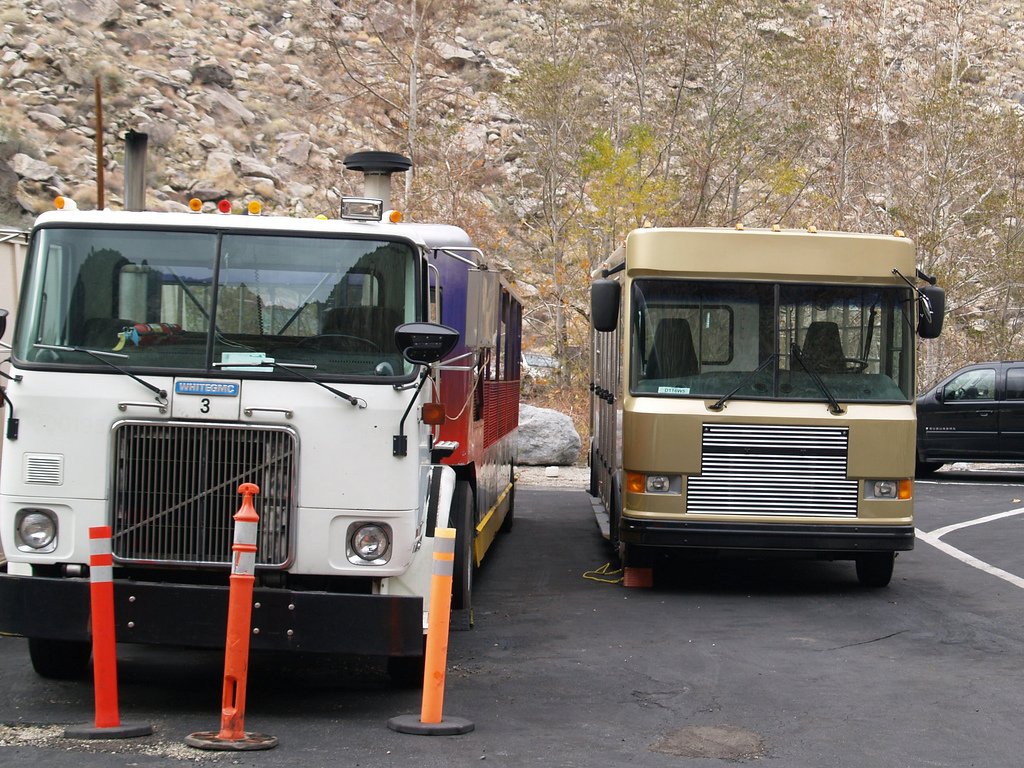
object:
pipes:
[124, 126, 146, 210]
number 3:
[200, 398, 209, 415]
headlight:
[343, 520, 392, 566]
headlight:
[11, 507, 58, 554]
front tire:
[618, 542, 654, 580]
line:
[914, 506, 1023, 590]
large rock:
[518, 402, 583, 463]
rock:
[432, 39, 493, 95]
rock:
[329, 12, 401, 73]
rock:
[254, 28, 326, 102]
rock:
[258, 121, 323, 206]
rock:
[180, 121, 279, 201]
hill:
[0, 4, 1024, 467]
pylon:
[386, 528, 477, 736]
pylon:
[184, 484, 275, 750]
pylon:
[58, 525, 153, 741]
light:
[381, 208, 405, 223]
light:
[246, 201, 263, 215]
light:
[217, 198, 231, 212]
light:
[187, 198, 204, 215]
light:
[55, 194, 72, 213]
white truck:
[0, 126, 523, 691]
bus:
[587, 220, 945, 589]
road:
[0, 466, 1022, 766]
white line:
[915, 503, 1024, 586]